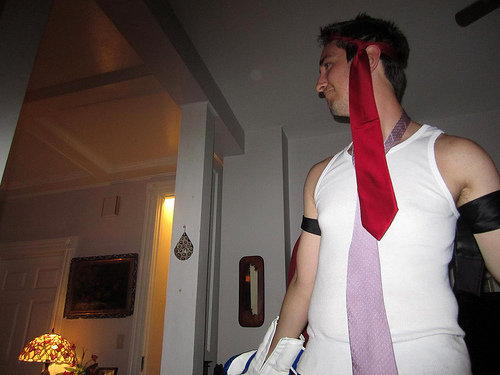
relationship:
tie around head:
[329, 32, 400, 243] [313, 12, 410, 121]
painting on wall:
[63, 251, 141, 321] [0, 179, 150, 373]